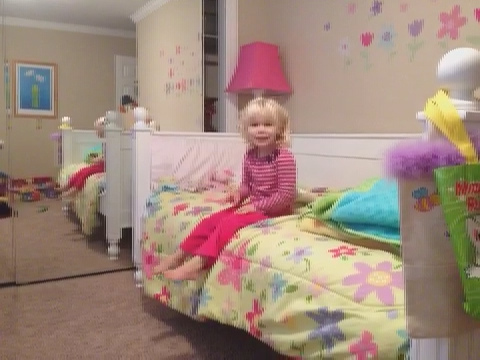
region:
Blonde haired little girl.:
[204, 96, 352, 237]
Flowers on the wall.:
[309, 16, 461, 63]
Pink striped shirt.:
[170, 140, 334, 240]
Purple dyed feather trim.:
[351, 130, 479, 186]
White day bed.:
[114, 89, 478, 324]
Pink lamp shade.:
[200, 30, 300, 95]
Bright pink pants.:
[171, 192, 291, 278]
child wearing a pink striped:
[234, 129, 290, 208]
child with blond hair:
[227, 83, 303, 156]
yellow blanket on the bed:
[156, 177, 413, 349]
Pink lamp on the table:
[217, 30, 308, 123]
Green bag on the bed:
[430, 151, 471, 324]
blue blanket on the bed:
[326, 160, 416, 252]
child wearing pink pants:
[178, 189, 272, 271]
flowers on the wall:
[315, 10, 463, 64]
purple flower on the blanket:
[340, 253, 412, 324]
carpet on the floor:
[36, 274, 146, 350]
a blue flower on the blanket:
[305, 306, 343, 343]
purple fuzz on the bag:
[389, 141, 463, 176]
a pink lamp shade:
[224, 42, 291, 94]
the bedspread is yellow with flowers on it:
[140, 177, 406, 358]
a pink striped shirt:
[231, 150, 296, 210]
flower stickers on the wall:
[335, 6, 473, 71]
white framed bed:
[133, 47, 477, 265]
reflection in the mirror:
[0, 0, 139, 278]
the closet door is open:
[203, 0, 216, 128]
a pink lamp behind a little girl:
[229, 43, 292, 98]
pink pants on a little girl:
[178, 202, 269, 259]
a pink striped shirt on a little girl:
[230, 145, 300, 209]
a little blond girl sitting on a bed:
[145, 97, 294, 285]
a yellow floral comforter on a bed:
[141, 183, 416, 359]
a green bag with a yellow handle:
[426, 89, 478, 310]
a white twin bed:
[129, 47, 478, 357]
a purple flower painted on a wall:
[406, 17, 431, 66]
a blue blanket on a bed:
[328, 176, 408, 248]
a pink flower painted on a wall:
[435, 4, 469, 45]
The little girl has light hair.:
[233, 99, 298, 144]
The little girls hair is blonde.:
[233, 97, 305, 156]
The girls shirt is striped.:
[223, 144, 305, 213]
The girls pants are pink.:
[183, 200, 263, 264]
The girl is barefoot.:
[142, 247, 214, 288]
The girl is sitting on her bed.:
[151, 90, 333, 331]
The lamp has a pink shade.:
[221, 31, 303, 100]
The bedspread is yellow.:
[238, 227, 388, 354]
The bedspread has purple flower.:
[336, 256, 400, 310]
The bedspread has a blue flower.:
[264, 264, 293, 301]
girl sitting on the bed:
[141, 98, 297, 278]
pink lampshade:
[222, 35, 291, 93]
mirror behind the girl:
[0, 2, 255, 299]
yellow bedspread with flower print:
[149, 177, 411, 359]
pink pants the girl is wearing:
[177, 205, 254, 255]